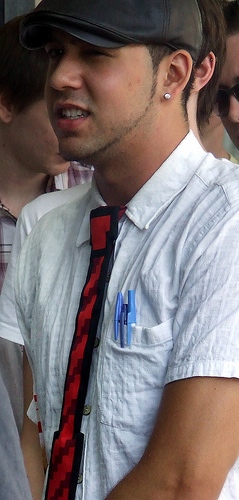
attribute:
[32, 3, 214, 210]
man — light-skinned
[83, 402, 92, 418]
button — round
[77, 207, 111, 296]
tie — red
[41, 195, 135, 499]
tie — necktie, black, red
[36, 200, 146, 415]
tie — red, black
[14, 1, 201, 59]
hat — black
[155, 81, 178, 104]
earring — diamond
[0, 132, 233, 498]
shirt — white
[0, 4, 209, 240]
male — young adult, red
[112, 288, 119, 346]
pen — three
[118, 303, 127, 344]
pen — three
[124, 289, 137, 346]
pen — three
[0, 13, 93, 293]
lady — light-skinned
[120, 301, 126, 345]
pen — blue, lidded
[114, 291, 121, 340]
pen — blue, lidded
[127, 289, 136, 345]
pen — blue, lidded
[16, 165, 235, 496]
shirt — wrinkled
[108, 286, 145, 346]
pens — blue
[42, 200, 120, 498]
tie — black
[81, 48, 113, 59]
eye — closed